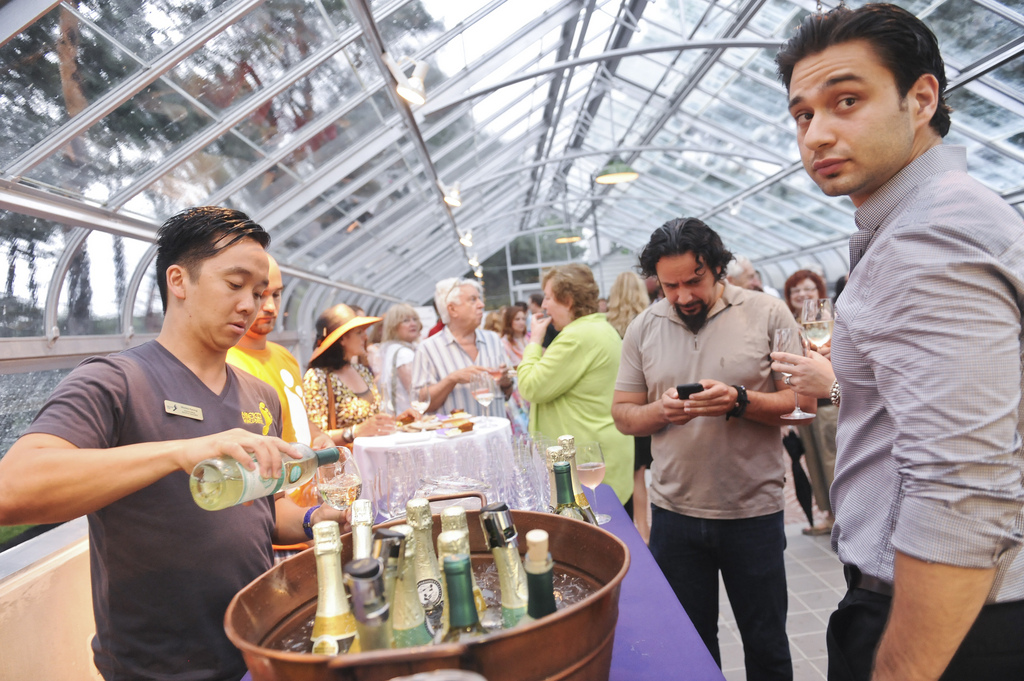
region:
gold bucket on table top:
[193, 480, 669, 664]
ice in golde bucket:
[561, 572, 577, 596]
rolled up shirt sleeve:
[880, 338, 1004, 569]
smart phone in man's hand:
[662, 373, 733, 431]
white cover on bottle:
[283, 496, 370, 585]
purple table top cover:
[634, 619, 726, 678]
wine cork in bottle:
[515, 517, 566, 578]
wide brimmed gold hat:
[287, 280, 405, 378]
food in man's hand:
[423, 335, 576, 409]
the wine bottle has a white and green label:
[193, 443, 359, 511]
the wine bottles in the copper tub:
[222, 490, 630, 678]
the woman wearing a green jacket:
[516, 262, 634, 532]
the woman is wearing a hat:
[302, 304, 395, 445]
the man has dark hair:
[612, 211, 809, 679]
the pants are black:
[646, 500, 793, 677]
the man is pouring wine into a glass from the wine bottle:
[1, 202, 359, 678]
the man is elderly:
[412, 275, 517, 441]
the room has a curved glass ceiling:
[0, 0, 1021, 678]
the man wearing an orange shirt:
[226, 252, 337, 547]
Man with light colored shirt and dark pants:
[776, 4, 1005, 671]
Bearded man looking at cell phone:
[601, 209, 816, 672]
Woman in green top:
[507, 255, 638, 519]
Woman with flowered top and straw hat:
[301, 288, 394, 453]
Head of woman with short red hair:
[779, 262, 833, 321]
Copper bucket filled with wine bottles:
[207, 487, 640, 671]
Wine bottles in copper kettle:
[298, 481, 565, 659]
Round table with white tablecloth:
[340, 402, 544, 527]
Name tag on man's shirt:
[153, 388, 212, 426]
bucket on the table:
[205, 479, 630, 677]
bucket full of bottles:
[207, 476, 642, 677]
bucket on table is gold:
[218, 477, 634, 677]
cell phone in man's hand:
[667, 368, 713, 414]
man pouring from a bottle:
[0, 188, 349, 678]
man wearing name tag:
[153, 391, 205, 421]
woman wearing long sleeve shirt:
[518, 309, 654, 515]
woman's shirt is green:
[512, 308, 646, 514]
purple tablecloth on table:
[226, 435, 718, 677]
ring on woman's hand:
[775, 366, 794, 390]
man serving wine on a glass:
[0, 178, 367, 669]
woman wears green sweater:
[511, 243, 651, 509]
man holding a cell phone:
[588, 200, 822, 510]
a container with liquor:
[217, 472, 654, 678]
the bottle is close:
[297, 510, 378, 663]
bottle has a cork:
[506, 515, 570, 623]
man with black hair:
[403, 258, 528, 423]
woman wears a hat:
[296, 284, 396, 424]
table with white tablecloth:
[332, 393, 528, 514]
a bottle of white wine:
[182, 429, 363, 519]